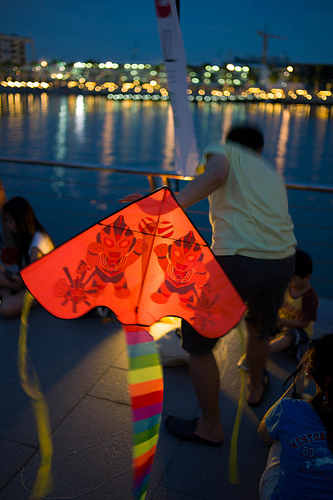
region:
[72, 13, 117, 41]
blue sky above water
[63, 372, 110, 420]
lines on the ground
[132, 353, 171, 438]
rainbow colored part of kite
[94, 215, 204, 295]
two figures on the kite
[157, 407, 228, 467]
shoe on the foot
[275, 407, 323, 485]
blue shirt on person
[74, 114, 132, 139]
reflection of light in water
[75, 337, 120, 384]
light hitting the ground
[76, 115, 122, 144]
water next to people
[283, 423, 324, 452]
word on back of shirt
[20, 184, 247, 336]
red kite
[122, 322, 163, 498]
wide, rainbow colored tail in the center of the kite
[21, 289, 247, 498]
yellow tails on the corners of the kite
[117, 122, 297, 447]
person holding the kite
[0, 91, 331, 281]
water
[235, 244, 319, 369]
boy sitting on the ground by the person with the kite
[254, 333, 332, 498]
girl sitting on the ground next to the person with the kite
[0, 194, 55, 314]
girl sitting on the ground by the fence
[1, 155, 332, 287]
metal fence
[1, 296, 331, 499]
paved sidewalk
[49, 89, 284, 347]
man holds orange kite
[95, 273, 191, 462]
kite has rainbow tail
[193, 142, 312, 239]
man has white shirt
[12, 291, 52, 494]
yellow ribbon on kite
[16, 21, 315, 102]
lit up skyline in distance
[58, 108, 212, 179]
water is dead calm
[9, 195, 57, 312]
woman sitting near railing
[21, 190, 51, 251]
woman has long hair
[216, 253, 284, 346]
person has dark shorts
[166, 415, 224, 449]
person is wearing sandals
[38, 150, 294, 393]
this man is having fun with a kite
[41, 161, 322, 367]
these people have their kites on a bridge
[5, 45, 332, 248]
the city lights are shining inthe background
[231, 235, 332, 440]
kids in the background on the bridge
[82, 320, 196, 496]
the kite's tail is colorful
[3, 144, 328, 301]
there is rail in front of the people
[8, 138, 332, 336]
the people are on a bridge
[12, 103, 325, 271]
the water is calm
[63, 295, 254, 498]
a light shines on the pavement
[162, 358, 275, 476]
this man has on slip on shoes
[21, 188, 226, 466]
Red Kite with tail.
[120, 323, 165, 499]
Multi-color tail.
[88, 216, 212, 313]
Two ancient men.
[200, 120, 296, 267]
Man with yellow shirt.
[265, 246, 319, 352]
A little boy sitting down.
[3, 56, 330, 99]
Lights on the shore.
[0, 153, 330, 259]
A steel balcony for safety.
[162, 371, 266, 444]
Pull-on shoes.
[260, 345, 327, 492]
A little girl with a blue t-shirt.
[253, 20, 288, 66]
Silhouette of a crane.